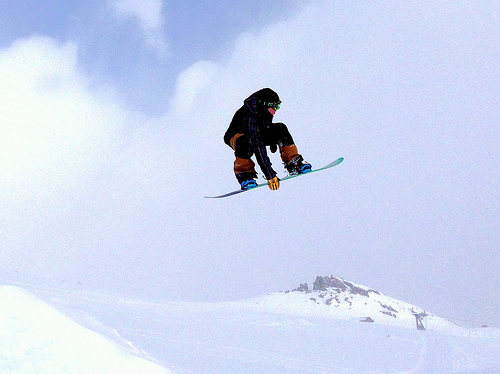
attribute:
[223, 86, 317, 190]
man — wearing, tricking, midair, jumping, snowboarding, stunting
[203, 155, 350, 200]
snowboard — blue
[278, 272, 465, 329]
mountain — distant, snowy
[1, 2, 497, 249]
sky — blue, cloudy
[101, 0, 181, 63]
clouds — white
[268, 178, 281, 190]
glove — yellow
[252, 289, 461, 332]
snow — white